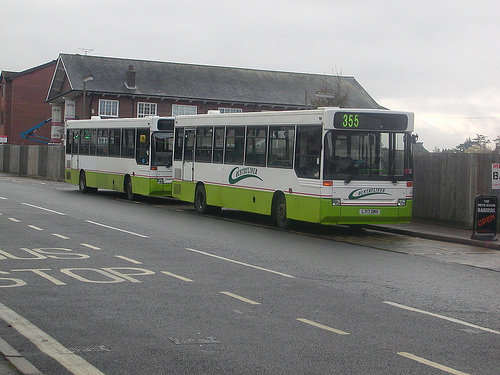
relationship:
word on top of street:
[1, 265, 156, 289] [1, 176, 499, 375]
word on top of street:
[0, 246, 91, 263] [1, 176, 499, 375]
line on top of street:
[20, 200, 66, 218] [1, 176, 499, 375]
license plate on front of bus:
[358, 207, 381, 216] [170, 106, 415, 231]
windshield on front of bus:
[320, 129, 413, 183] [170, 106, 415, 231]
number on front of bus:
[341, 113, 360, 129] [170, 106, 415, 231]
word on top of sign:
[475, 213, 495, 229] [470, 195, 499, 242]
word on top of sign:
[477, 199, 496, 215] [470, 195, 499, 242]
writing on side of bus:
[228, 165, 263, 182] [170, 106, 415, 231]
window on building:
[97, 98, 120, 119] [1, 53, 393, 147]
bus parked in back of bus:
[64, 114, 173, 202] [170, 106, 415, 231]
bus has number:
[170, 106, 415, 231] [341, 113, 360, 129]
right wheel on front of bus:
[273, 194, 290, 231] [170, 106, 415, 231]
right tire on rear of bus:
[193, 184, 207, 212] [170, 106, 415, 231]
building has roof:
[1, 53, 393, 147] [44, 54, 389, 111]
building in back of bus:
[1, 53, 393, 147] [64, 114, 173, 202]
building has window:
[1, 53, 393, 147] [97, 98, 120, 119]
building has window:
[1, 53, 393, 147] [134, 101, 158, 119]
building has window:
[1, 53, 393, 147] [171, 102, 197, 117]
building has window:
[1, 53, 393, 147] [218, 106, 242, 115]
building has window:
[1, 53, 393, 147] [63, 100, 77, 118]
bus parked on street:
[170, 106, 415, 231] [1, 176, 499, 375]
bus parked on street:
[64, 114, 173, 202] [1, 176, 499, 375]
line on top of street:
[84, 218, 148, 240] [1, 176, 499, 375]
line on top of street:
[184, 246, 296, 283] [1, 176, 499, 375]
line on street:
[20, 200, 66, 218] [1, 176, 499, 375]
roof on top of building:
[44, 54, 389, 111] [1, 53, 393, 147]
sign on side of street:
[470, 195, 499, 242] [1, 176, 499, 375]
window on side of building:
[63, 100, 77, 118] [1, 53, 393, 147]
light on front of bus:
[330, 197, 343, 207] [170, 106, 415, 231]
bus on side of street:
[170, 106, 415, 231] [1, 176, 499, 375]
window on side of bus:
[265, 125, 297, 171] [170, 106, 415, 231]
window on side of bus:
[243, 123, 267, 166] [170, 106, 415, 231]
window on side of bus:
[222, 125, 248, 167] [170, 106, 415, 231]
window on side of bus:
[210, 126, 227, 166] [170, 106, 415, 231]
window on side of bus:
[193, 126, 214, 165] [170, 106, 415, 231]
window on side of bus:
[119, 127, 137, 162] [64, 114, 173, 202]